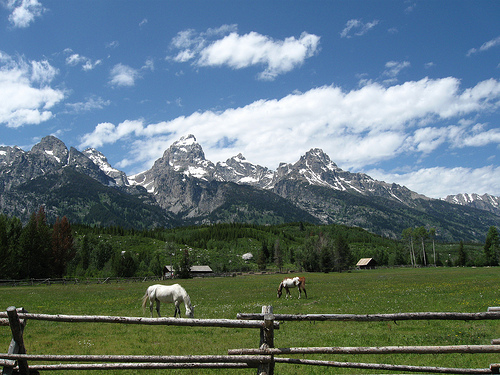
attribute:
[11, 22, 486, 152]
clouds — white 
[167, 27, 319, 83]
clouds — white 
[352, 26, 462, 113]
sky — blue 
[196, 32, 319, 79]
cloud — white 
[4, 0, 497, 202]
sky — blue 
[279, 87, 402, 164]
clouds — white 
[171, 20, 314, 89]
cumulus cloud — large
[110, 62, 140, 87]
cloud — white 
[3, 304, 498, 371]
wooden fence — wooden  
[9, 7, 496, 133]
sky — blue 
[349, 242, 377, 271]
house — small 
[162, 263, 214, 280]
house — larger 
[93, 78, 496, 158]
clouds — white 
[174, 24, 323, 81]
cloud — white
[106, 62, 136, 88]
cloud — white 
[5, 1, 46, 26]
clouds — white 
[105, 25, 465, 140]
clouds — white 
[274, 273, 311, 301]
horse — brown, white 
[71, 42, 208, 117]
sky — blue 